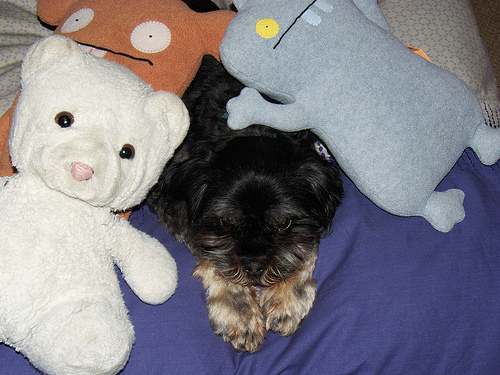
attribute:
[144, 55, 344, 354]
dog — black, brown, small, angry, yorkie, puppy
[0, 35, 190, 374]
stuffed animal — white, teddy bear, bear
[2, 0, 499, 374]
bed — blue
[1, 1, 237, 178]
stuffed animal — orange, cartoon character, from nickelodeon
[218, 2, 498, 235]
stuffed animal — grey, gray, cartoon character, from nickelodeon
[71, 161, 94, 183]
nose — pink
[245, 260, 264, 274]
nose — black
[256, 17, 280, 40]
eye — yellow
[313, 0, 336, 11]
tooth — white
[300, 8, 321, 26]
tooth — white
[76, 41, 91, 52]
tooth — white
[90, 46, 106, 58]
tooth — white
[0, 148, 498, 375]
blanket — blue, purple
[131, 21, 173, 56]
eye — white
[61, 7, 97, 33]
eye — white